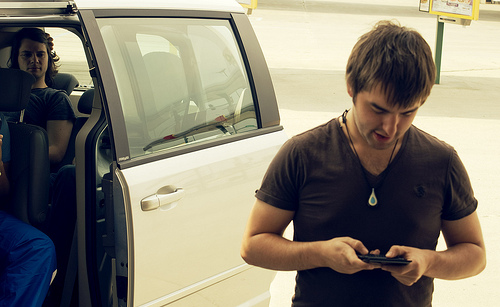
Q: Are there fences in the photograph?
A: No, there are no fences.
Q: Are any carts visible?
A: No, there are no carts.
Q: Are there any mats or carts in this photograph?
A: No, there are no carts or mats.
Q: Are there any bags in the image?
A: No, there are no bags.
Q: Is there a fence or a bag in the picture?
A: No, there are no bags or fences.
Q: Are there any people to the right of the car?
A: Yes, there is a person to the right of the car.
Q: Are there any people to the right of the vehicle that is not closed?
A: Yes, there is a person to the right of the car.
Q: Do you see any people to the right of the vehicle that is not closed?
A: Yes, there is a person to the right of the car.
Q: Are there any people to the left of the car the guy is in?
A: No, the person is to the right of the car.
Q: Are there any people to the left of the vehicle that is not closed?
A: No, the person is to the right of the car.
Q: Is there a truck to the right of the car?
A: No, there is a person to the right of the car.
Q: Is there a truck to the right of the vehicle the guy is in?
A: No, there is a person to the right of the car.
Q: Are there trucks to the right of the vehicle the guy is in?
A: No, there is a person to the right of the car.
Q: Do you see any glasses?
A: No, there are no glasses.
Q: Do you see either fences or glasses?
A: No, there are no glasses or fences.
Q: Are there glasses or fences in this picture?
A: No, there are no glasses or fences.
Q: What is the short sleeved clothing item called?
A: The clothing item is a shirt.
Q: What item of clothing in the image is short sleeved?
A: The clothing item is a shirt.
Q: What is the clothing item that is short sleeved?
A: The clothing item is a shirt.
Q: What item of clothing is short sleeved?
A: The clothing item is a shirt.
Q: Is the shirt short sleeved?
A: Yes, the shirt is short sleeved.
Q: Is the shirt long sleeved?
A: No, the shirt is short sleeved.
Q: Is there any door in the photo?
A: Yes, there is a door.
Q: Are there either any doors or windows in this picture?
A: Yes, there is a door.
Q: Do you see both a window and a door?
A: Yes, there are both a door and a window.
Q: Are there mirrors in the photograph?
A: No, there are no mirrors.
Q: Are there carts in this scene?
A: No, there are no carts.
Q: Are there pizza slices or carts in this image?
A: No, there are no carts or pizza slices.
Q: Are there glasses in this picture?
A: No, there are no glasses.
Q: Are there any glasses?
A: No, there are no glasses.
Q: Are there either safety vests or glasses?
A: No, there are no glasses or safety vests.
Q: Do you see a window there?
A: Yes, there is a window.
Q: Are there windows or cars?
A: Yes, there is a window.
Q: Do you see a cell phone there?
A: Yes, there is a cell phone.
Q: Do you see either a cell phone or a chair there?
A: Yes, there is a cell phone.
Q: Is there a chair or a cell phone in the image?
A: Yes, there is a cell phone.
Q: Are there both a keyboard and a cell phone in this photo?
A: No, there is a cell phone but no keyboards.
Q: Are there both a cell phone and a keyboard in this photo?
A: No, there is a cell phone but no keyboards.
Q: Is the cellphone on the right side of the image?
A: Yes, the cellphone is on the right of the image.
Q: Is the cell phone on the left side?
A: No, the cell phone is on the right of the image.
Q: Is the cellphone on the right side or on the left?
A: The cellphone is on the right of the image.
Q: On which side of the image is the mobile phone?
A: The mobile phone is on the right of the image.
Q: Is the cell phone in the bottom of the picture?
A: Yes, the cell phone is in the bottom of the image.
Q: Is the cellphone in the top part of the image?
A: No, the cellphone is in the bottom of the image.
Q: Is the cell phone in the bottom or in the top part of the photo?
A: The cell phone is in the bottom of the image.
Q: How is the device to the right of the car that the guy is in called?
A: The device is a cell phone.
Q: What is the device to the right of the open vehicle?
A: The device is a cell phone.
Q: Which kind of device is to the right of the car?
A: The device is a cell phone.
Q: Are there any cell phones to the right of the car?
A: Yes, there is a cell phone to the right of the car.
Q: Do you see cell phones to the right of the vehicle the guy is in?
A: Yes, there is a cell phone to the right of the car.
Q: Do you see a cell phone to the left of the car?
A: No, the cell phone is to the right of the car.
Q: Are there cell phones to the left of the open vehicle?
A: No, the cell phone is to the right of the car.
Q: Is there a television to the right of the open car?
A: No, there is a cell phone to the right of the car.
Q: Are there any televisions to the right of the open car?
A: No, there is a cell phone to the right of the car.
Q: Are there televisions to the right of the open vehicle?
A: No, there is a cell phone to the right of the car.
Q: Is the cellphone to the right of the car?
A: Yes, the cellphone is to the right of the car.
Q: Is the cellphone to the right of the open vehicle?
A: Yes, the cellphone is to the right of the car.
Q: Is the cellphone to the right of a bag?
A: No, the cellphone is to the right of the car.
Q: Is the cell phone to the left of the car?
A: No, the cell phone is to the right of the car.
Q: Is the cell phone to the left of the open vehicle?
A: No, the cell phone is to the right of the car.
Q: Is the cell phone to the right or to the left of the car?
A: The cell phone is to the right of the car.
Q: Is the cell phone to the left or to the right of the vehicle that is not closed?
A: The cell phone is to the right of the car.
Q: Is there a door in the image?
A: Yes, there is a door.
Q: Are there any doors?
A: Yes, there is a door.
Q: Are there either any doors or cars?
A: Yes, there is a door.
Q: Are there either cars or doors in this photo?
A: Yes, there is a door.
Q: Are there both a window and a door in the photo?
A: Yes, there are both a door and a window.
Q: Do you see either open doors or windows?
A: Yes, there is an open door.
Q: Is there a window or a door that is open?
A: Yes, the door is open.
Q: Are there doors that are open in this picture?
A: Yes, there is an open door.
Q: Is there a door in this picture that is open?
A: Yes, there is a door that is open.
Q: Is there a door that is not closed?
A: Yes, there is a open door.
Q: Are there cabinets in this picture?
A: No, there are no cabinets.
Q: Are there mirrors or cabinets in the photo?
A: No, there are no cabinets or mirrors.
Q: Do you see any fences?
A: No, there are no fences.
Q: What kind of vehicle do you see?
A: The vehicle is a car.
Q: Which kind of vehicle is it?
A: The vehicle is a car.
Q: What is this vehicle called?
A: That is a car.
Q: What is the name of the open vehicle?
A: The vehicle is a car.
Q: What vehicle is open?
A: The vehicle is a car.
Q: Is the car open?
A: Yes, the car is open.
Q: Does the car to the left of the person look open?
A: Yes, the car is open.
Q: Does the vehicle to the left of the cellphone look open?
A: Yes, the car is open.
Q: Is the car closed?
A: No, the car is open.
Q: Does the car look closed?
A: No, the car is open.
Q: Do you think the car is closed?
A: No, the car is open.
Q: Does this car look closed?
A: No, the car is open.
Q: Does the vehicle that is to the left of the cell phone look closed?
A: No, the car is open.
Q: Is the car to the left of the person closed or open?
A: The car is open.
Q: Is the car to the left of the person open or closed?
A: The car is open.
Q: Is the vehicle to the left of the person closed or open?
A: The car is open.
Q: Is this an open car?
A: Yes, this is an open car.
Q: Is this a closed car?
A: No, this is an open car.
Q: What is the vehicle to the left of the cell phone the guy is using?
A: The vehicle is a car.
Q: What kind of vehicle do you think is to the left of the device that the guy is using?
A: The vehicle is a car.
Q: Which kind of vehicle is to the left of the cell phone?
A: The vehicle is a car.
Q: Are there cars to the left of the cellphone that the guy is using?
A: Yes, there is a car to the left of the mobile phone.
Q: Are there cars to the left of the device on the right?
A: Yes, there is a car to the left of the mobile phone.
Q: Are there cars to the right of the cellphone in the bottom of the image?
A: No, the car is to the left of the cell phone.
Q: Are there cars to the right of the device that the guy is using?
A: No, the car is to the left of the cell phone.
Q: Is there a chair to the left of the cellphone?
A: No, there is a car to the left of the cellphone.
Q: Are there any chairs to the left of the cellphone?
A: No, there is a car to the left of the cellphone.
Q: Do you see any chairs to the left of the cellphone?
A: No, there is a car to the left of the cellphone.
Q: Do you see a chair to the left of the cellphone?
A: No, there is a car to the left of the cellphone.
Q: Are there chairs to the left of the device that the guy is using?
A: No, there is a car to the left of the cellphone.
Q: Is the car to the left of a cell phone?
A: Yes, the car is to the left of a cell phone.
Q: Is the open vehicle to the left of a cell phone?
A: Yes, the car is to the left of a cell phone.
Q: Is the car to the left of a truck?
A: No, the car is to the left of a cell phone.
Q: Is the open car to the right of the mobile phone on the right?
A: No, the car is to the left of the mobile phone.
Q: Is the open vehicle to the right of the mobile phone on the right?
A: No, the car is to the left of the mobile phone.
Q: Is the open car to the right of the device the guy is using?
A: No, the car is to the left of the mobile phone.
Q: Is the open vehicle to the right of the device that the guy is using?
A: No, the car is to the left of the mobile phone.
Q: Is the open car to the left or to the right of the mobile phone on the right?
A: The car is to the left of the cellphone.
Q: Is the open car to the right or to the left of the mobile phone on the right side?
A: The car is to the left of the cellphone.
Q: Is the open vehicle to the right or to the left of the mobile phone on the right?
A: The car is to the left of the cellphone.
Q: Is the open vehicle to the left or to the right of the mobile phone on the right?
A: The car is to the left of the cellphone.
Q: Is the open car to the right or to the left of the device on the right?
A: The car is to the left of the cellphone.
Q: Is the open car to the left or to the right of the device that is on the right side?
A: The car is to the left of the cellphone.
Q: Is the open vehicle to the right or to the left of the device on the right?
A: The car is to the left of the cellphone.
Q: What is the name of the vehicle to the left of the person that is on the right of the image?
A: The vehicle is a car.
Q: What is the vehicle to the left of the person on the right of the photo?
A: The vehicle is a car.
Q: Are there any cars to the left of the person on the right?
A: Yes, there is a car to the left of the person.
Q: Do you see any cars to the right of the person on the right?
A: No, the car is to the left of the person.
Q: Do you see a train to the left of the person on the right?
A: No, there is a car to the left of the person.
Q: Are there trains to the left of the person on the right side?
A: No, there is a car to the left of the person.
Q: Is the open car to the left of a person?
A: Yes, the car is to the left of a person.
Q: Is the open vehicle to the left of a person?
A: Yes, the car is to the left of a person.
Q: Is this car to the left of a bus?
A: No, the car is to the left of a person.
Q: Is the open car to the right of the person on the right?
A: No, the car is to the left of the person.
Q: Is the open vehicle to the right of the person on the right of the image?
A: No, the car is to the left of the person.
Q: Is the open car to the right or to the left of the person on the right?
A: The car is to the left of the person.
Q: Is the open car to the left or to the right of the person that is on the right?
A: The car is to the left of the person.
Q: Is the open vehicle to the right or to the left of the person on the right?
A: The car is to the left of the person.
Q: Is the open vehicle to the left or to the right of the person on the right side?
A: The car is to the left of the person.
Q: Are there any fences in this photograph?
A: No, there are no fences.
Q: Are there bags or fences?
A: No, there are no fences or bags.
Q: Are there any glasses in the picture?
A: No, there are no glasses.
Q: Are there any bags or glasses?
A: No, there are no glasses or bags.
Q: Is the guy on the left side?
A: Yes, the guy is on the left of the image.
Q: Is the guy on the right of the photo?
A: No, the guy is on the left of the image.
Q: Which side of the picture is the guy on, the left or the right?
A: The guy is on the left of the image.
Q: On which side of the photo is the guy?
A: The guy is on the left of the image.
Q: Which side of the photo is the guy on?
A: The guy is on the left of the image.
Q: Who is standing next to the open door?
A: The guy is standing next to the door.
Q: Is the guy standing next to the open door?
A: Yes, the guy is standing next to the door.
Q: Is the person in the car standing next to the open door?
A: Yes, the guy is standing next to the door.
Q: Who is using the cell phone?
A: The guy is using the cell phone.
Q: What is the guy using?
A: The guy is using a mobile phone.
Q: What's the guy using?
A: The guy is using a mobile phone.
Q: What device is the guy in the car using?
A: The guy is using a cellphone.